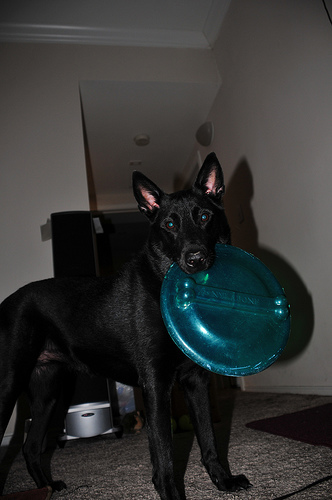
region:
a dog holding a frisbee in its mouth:
[1, 147, 292, 498]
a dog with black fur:
[0, 151, 250, 494]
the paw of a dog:
[205, 464, 251, 495]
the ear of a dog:
[191, 150, 225, 198]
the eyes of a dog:
[163, 210, 212, 231]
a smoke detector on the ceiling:
[133, 132, 152, 149]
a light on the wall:
[193, 120, 213, 146]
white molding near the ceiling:
[0, 20, 210, 52]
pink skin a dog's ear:
[202, 150, 222, 192]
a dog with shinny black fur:
[5, 149, 253, 496]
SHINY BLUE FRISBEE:
[162, 246, 296, 372]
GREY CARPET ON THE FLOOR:
[0, 394, 327, 492]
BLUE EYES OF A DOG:
[158, 210, 217, 231]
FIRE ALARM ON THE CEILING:
[133, 132, 151, 150]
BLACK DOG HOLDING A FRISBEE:
[4, 149, 308, 491]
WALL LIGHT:
[191, 118, 218, 147]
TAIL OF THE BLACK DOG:
[1, 393, 33, 483]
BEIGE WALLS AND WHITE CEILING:
[3, 1, 331, 168]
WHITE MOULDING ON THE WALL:
[0, 2, 230, 54]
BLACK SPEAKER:
[45, 205, 102, 277]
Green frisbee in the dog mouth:
[161, 238, 299, 378]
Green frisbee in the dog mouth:
[132, 158, 312, 450]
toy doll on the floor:
[117, 398, 151, 436]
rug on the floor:
[246, 380, 331, 461]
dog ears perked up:
[118, 151, 245, 216]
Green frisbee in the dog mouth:
[115, 138, 291, 382]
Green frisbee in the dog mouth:
[126, 156, 292, 380]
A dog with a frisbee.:
[2, 151, 291, 498]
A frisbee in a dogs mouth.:
[158, 242, 292, 377]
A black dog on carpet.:
[2, 150, 252, 497]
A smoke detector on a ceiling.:
[132, 132, 152, 146]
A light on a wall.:
[194, 117, 214, 148]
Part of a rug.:
[243, 399, 330, 450]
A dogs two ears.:
[130, 151, 226, 222]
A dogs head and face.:
[151, 188, 224, 276]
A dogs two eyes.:
[163, 210, 209, 231]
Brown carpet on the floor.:
[1, 389, 331, 497]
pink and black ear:
[123, 157, 161, 220]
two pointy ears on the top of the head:
[126, 150, 229, 204]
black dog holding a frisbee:
[2, 152, 301, 497]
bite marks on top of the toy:
[239, 244, 258, 258]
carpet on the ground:
[0, 388, 331, 499]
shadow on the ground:
[166, 424, 195, 498]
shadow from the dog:
[170, 426, 196, 499]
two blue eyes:
[162, 211, 215, 237]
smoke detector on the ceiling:
[128, 132, 155, 147]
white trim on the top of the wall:
[1, 21, 208, 54]